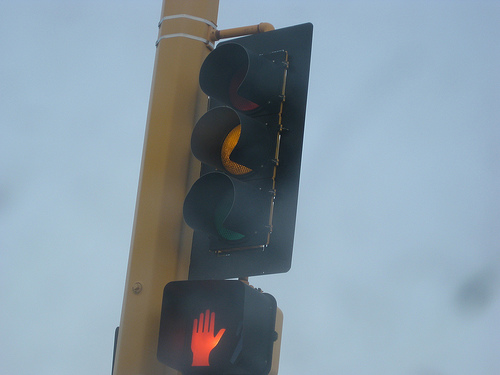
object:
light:
[220, 64, 274, 114]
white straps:
[156, 14, 217, 28]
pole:
[111, 1, 222, 375]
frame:
[188, 23, 315, 280]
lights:
[220, 121, 252, 174]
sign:
[161, 280, 238, 369]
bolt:
[132, 283, 143, 296]